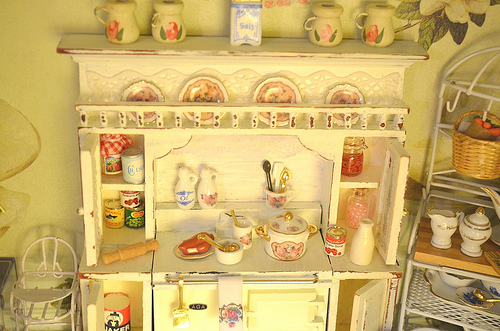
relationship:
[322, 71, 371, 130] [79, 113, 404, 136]
plate on shelf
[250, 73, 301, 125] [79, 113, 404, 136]
plate on shelf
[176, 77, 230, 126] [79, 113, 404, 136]
plate on shelf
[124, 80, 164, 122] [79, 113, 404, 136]
plate on shelf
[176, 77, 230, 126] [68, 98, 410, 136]
plate on shelf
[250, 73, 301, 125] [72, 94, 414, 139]
plate on shelf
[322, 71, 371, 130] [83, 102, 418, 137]
plate on shelf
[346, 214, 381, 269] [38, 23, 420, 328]
vase on table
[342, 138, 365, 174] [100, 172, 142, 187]
jar on shelf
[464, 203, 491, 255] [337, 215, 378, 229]
jar on shelf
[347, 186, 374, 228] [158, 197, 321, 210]
jar on shelf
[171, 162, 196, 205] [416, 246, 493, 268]
jar on shelf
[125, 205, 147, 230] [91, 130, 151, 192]
can on shelf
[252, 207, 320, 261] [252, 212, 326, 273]
pot on plate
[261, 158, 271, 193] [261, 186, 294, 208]
spoon in cup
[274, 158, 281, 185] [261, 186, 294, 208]
spoon in cup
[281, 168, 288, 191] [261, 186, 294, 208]
spoon in cup